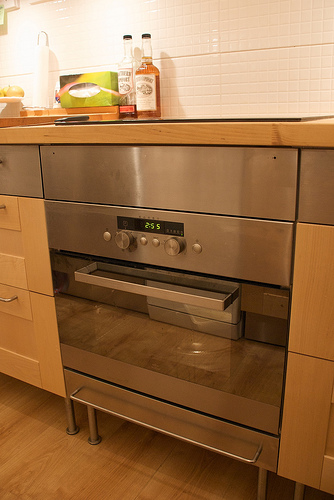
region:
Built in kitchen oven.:
[44, 200, 277, 471]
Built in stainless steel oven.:
[43, 200, 290, 473]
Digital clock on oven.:
[131, 219, 168, 233]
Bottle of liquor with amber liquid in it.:
[135, 32, 161, 117]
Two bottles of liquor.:
[120, 33, 160, 119]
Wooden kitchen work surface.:
[49, 121, 332, 145]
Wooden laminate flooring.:
[14, 441, 117, 491]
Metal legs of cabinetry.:
[61, 397, 101, 445]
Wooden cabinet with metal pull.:
[0, 284, 61, 392]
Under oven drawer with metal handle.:
[63, 370, 277, 471]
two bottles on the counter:
[114, 27, 167, 118]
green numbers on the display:
[140, 218, 164, 232]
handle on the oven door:
[73, 263, 245, 315]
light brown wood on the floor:
[0, 381, 316, 498]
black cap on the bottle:
[139, 31, 150, 38]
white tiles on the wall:
[0, 0, 332, 117]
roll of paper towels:
[27, 29, 57, 117]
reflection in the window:
[133, 277, 252, 344]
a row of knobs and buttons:
[96, 228, 209, 259]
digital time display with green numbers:
[134, 217, 161, 232]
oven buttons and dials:
[101, 226, 204, 259]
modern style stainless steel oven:
[45, 200, 290, 471]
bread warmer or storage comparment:
[57, 363, 283, 472]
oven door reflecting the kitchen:
[47, 246, 283, 431]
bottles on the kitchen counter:
[115, 32, 165, 116]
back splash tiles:
[190, 18, 288, 110]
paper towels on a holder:
[25, 29, 51, 107]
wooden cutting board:
[2, 105, 115, 127]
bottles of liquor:
[102, 8, 196, 143]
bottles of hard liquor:
[97, 12, 167, 130]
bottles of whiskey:
[103, 18, 192, 126]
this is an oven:
[38, 191, 316, 473]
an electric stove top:
[60, 98, 331, 139]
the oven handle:
[58, 250, 266, 328]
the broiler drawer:
[47, 353, 327, 478]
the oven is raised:
[61, 399, 289, 498]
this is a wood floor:
[2, 389, 273, 498]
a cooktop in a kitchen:
[57, 104, 331, 126]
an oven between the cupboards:
[30, 187, 332, 476]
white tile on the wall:
[185, 16, 326, 98]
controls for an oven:
[90, 211, 204, 255]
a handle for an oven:
[72, 263, 236, 321]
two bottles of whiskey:
[116, 25, 161, 122]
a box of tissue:
[53, 72, 119, 105]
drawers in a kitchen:
[4, 146, 51, 386]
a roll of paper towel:
[29, 20, 58, 111]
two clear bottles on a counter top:
[118, 31, 161, 118]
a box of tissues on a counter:
[56, 70, 122, 108]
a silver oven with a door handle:
[45, 192, 285, 442]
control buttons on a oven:
[112, 229, 189, 262]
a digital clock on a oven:
[133, 214, 171, 229]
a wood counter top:
[78, 119, 328, 149]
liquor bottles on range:
[111, 30, 173, 120]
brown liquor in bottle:
[130, 17, 171, 128]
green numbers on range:
[128, 218, 170, 231]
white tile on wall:
[190, 22, 294, 97]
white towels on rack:
[28, 35, 50, 102]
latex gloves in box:
[51, 73, 116, 100]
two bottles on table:
[118, 44, 164, 112]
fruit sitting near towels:
[1, 80, 31, 111]